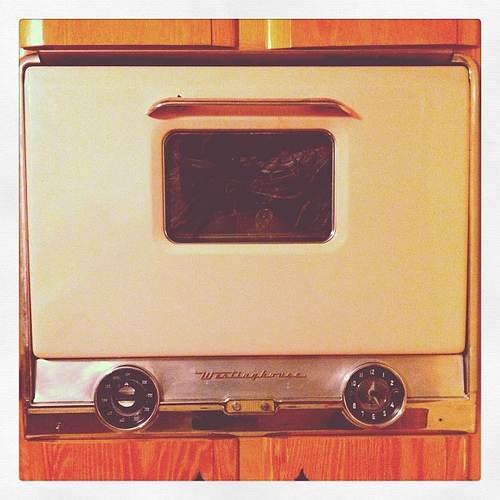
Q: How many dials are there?
A: Two.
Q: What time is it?
A: 12:25.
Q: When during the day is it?
A: 12:25.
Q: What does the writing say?
A: Westinghouse.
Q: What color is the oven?
A: White.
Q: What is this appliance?
A: An oven.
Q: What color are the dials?
A: Black.